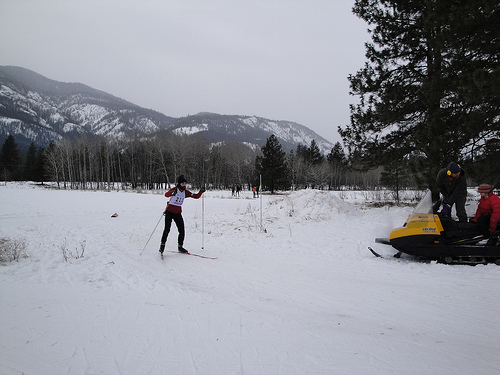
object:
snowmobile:
[366, 192, 499, 264]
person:
[156, 175, 205, 258]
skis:
[170, 246, 218, 260]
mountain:
[0, 65, 339, 160]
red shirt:
[164, 187, 201, 214]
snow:
[0, 180, 499, 374]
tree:
[335, 4, 499, 208]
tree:
[252, 132, 296, 193]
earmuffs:
[445, 159, 462, 176]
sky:
[1, 1, 499, 154]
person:
[432, 160, 468, 221]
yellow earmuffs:
[447, 160, 462, 175]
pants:
[160, 213, 186, 249]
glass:
[410, 187, 439, 222]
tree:
[43, 144, 64, 187]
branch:
[59, 243, 75, 263]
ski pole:
[199, 193, 207, 259]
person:
[453, 182, 499, 247]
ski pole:
[137, 192, 174, 257]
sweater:
[166, 188, 200, 214]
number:
[172, 195, 185, 203]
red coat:
[470, 193, 499, 234]